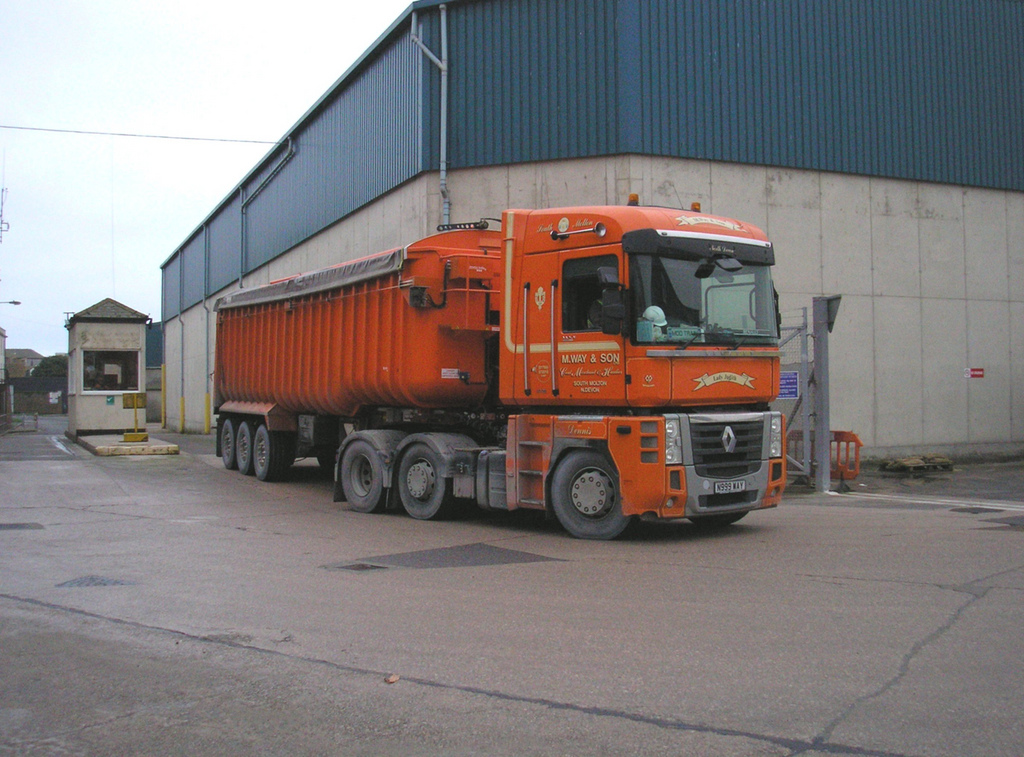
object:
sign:
[106, 395, 115, 405]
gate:
[778, 307, 830, 492]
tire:
[399, 445, 462, 520]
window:
[629, 254, 780, 347]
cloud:
[0, 0, 408, 321]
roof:
[65, 298, 148, 331]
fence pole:
[811, 297, 828, 494]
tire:
[551, 450, 631, 540]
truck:
[211, 193, 786, 540]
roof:
[161, 1, 1024, 322]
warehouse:
[158, 0, 1024, 471]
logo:
[722, 426, 739, 453]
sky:
[0, 0, 419, 235]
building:
[65, 298, 153, 435]